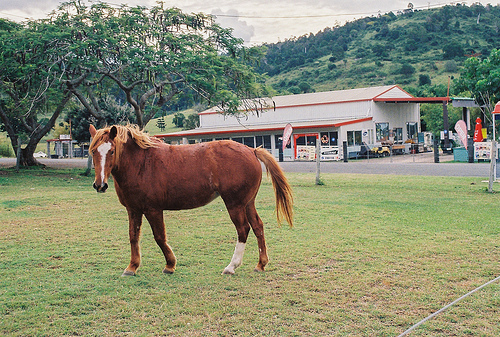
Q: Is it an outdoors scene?
A: Yes, it is outdoors.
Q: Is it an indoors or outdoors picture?
A: It is outdoors.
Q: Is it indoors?
A: No, it is outdoors.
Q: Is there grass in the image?
A: Yes, there is grass.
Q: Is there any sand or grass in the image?
A: Yes, there is grass.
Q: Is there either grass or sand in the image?
A: Yes, there is grass.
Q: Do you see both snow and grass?
A: No, there is grass but no snow.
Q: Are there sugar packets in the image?
A: No, there are no sugar packets.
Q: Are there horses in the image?
A: Yes, there is a horse.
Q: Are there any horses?
A: Yes, there is a horse.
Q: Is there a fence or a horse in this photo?
A: Yes, there is a horse.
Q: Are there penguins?
A: No, there are no penguins.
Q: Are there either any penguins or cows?
A: No, there are no penguins or cows.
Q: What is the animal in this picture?
A: The animal is a horse.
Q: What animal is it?
A: The animal is a horse.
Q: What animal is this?
A: That is a horse.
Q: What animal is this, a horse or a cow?
A: That is a horse.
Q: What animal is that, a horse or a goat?
A: That is a horse.